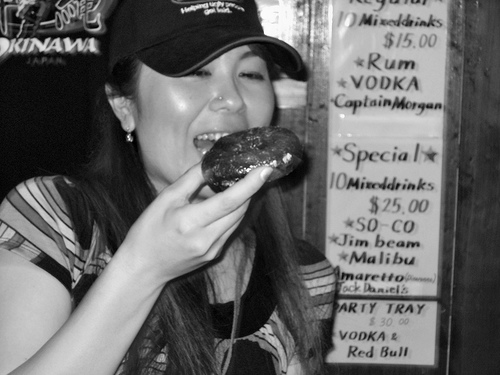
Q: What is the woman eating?
A: A donut.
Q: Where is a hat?
A: On woman's head.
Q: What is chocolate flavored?
A: The donut.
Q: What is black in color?
A: A hat.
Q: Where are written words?
A: On a menu.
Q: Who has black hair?
A: The woman.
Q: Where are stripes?
A: On woman's shirt.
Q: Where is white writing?
A: On the hat.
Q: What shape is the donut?
A: Round.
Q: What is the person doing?
A: Eating a donut.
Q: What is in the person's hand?
A: Donut.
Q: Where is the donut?
A: In the girl's hand.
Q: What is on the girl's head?
A: A hat.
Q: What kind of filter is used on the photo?
A: Black and white.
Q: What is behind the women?
A: Drink sign.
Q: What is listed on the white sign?
A: Drinks.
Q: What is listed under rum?
A: Vodka.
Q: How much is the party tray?
A: 30.00.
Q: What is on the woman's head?
A: Baseball cap.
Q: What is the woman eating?
A: Doughnut.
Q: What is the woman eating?
A: A donut.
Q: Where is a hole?
A: In the donut.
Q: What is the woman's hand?
A: A donut.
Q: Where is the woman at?
A: Outside or inside of a bar.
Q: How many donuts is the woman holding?
A: One.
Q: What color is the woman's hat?
A: Black.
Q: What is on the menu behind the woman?
A: Alcoholic beverages.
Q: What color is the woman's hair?
A: Brown.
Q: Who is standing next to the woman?
A: Noone.